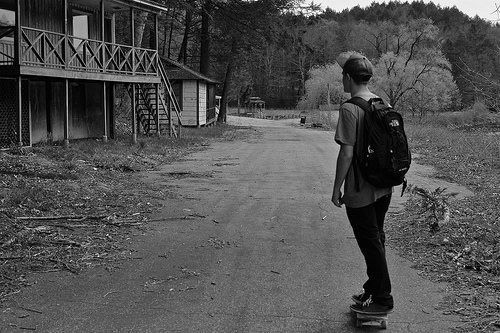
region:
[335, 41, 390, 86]
man is wearing cap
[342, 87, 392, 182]
man has black backpack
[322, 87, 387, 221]
man has grey shirt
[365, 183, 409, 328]
man has dark pants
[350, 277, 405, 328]
man has grey shoes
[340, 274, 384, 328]
man is on skateboard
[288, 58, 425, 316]
man is on dirt path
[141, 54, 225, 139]
small building in background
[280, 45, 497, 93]
trees are behind man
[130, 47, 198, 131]
ladder leads to second floor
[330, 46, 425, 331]
guy wearing a cap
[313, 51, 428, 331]
guy wearing a back pack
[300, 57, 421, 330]
guy wearing a short t-shirt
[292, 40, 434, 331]
guy riding on his skateboard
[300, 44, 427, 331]
guy is wearing a pair of sneakers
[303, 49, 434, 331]
guy is wearing jeans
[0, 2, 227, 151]
a cabin house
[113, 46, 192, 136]
stairs to a building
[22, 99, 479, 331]
a road leading towards a building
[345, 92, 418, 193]
a dark north face back pack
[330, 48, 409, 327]
man riding a skate board with a backpack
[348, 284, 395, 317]
black sneakers with white laces on a skate board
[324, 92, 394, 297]
black long pants and a light short sleeve shirt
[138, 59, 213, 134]
white wooden shed with a black roof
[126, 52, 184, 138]
stairs to second level of a home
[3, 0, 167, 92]
railed porch on the second floor of a home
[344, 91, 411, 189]
black back pack with a white logo on it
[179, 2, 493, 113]
small and large trees in the background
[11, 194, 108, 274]
debri laying on the side of a road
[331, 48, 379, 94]
head of a skate board rider with a cap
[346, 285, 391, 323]
he is on the skateboard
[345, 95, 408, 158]
the pack is on his back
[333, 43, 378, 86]
he is wearing a hat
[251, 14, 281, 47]
the tree has leaves on it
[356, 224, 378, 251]
his pants are black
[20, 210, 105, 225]
the limb is on the ground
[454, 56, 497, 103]
the tree is bare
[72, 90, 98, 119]
the wall is weathered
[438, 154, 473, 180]
the leaves are on the ground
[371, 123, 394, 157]
the pack is a dark color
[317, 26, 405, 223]
a man with a back pack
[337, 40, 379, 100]
a man wearing a cap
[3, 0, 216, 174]
a building with a porch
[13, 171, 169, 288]
tree branches that have fallen to the ground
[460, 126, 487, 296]
leaves and twigs on the ground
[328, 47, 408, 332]
a man riding a skateboard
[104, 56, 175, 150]
a set of wood stairs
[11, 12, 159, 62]
wood porch post on a building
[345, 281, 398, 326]
a man wearing shoes with white laces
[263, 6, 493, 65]
a hillside covered with trees